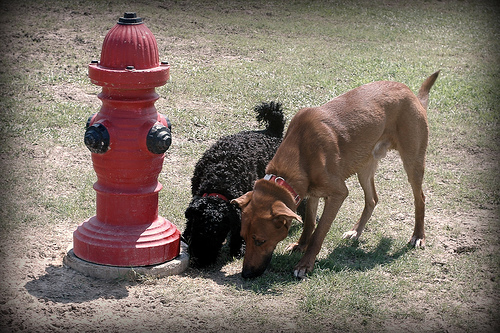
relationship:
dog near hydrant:
[182, 97, 288, 267] [72, 11, 180, 265]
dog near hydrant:
[231, 67, 440, 278] [72, 11, 180, 265]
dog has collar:
[182, 97, 288, 267] [196, 190, 231, 202]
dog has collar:
[231, 67, 440, 278] [263, 173, 304, 207]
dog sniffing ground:
[182, 97, 288, 267] [4, 3, 499, 331]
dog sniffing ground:
[231, 67, 440, 278] [4, 3, 499, 331]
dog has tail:
[182, 97, 288, 267] [251, 101, 289, 136]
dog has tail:
[231, 67, 440, 278] [413, 69, 441, 111]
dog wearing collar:
[182, 97, 288, 267] [196, 190, 231, 202]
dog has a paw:
[182, 97, 288, 267] [226, 243, 240, 258]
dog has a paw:
[231, 67, 440, 278] [290, 256, 319, 278]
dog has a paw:
[231, 67, 440, 278] [284, 242, 302, 255]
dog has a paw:
[231, 67, 440, 278] [342, 230, 363, 248]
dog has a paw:
[231, 67, 440, 278] [408, 232, 426, 250]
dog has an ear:
[182, 97, 288, 267] [182, 200, 206, 240]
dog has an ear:
[182, 97, 288, 267] [224, 203, 241, 256]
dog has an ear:
[231, 67, 440, 278] [230, 193, 252, 212]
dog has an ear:
[231, 67, 440, 278] [271, 200, 304, 227]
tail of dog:
[251, 101, 289, 136] [182, 97, 288, 267]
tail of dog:
[413, 69, 441, 111] [231, 67, 440, 278]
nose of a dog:
[192, 257, 207, 267] [182, 97, 288, 267]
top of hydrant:
[100, 12, 160, 69] [72, 11, 180, 265]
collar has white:
[263, 173, 304, 207] [261, 171, 274, 183]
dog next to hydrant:
[182, 97, 288, 267] [72, 11, 180, 265]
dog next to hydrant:
[231, 67, 440, 278] [72, 11, 180, 265]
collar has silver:
[263, 173, 304, 207] [272, 176, 286, 184]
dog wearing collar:
[231, 67, 440, 278] [263, 173, 304, 207]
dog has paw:
[182, 97, 288, 267] [226, 243, 240, 258]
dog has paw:
[231, 67, 440, 278] [290, 256, 319, 278]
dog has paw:
[231, 67, 440, 278] [284, 242, 302, 255]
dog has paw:
[231, 67, 440, 278] [342, 230, 363, 248]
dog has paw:
[231, 67, 440, 278] [408, 232, 426, 250]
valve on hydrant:
[115, 11, 145, 23] [72, 11, 180, 265]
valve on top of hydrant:
[115, 11, 145, 23] [72, 11, 180, 265]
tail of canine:
[251, 101, 289, 136] [182, 97, 288, 267]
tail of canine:
[413, 69, 441, 111] [231, 67, 440, 278]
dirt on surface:
[99, 288, 211, 322] [4, 3, 499, 331]